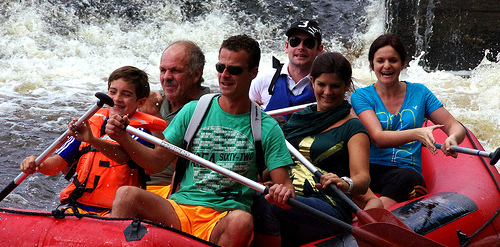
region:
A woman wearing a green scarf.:
[281, 70, 361, 127]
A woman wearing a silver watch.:
[318, 153, 357, 193]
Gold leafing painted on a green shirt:
[293, 124, 345, 187]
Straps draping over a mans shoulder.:
[186, 90, 290, 160]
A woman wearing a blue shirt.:
[362, 77, 430, 189]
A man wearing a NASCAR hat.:
[281, 18, 345, 45]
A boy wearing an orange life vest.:
[63, 92, 142, 214]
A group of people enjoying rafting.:
[72, 33, 493, 223]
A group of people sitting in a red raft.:
[31, 28, 494, 244]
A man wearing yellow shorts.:
[143, 182, 252, 242]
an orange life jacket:
[82, 110, 134, 201]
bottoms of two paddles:
[351, 206, 436, 243]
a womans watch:
[340, 171, 362, 197]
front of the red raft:
[6, 210, 130, 245]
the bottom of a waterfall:
[11, 5, 143, 63]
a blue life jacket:
[274, 73, 311, 123]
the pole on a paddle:
[436, 144, 491, 152]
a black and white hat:
[284, 19, 325, 39]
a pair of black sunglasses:
[286, 33, 323, 51]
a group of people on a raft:
[63, 22, 448, 206]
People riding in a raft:
[1, 14, 498, 243]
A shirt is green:
[161, 92, 298, 213]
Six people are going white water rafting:
[1, 2, 498, 243]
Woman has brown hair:
[364, 30, 410, 83]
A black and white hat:
[282, 14, 328, 49]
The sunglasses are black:
[211, 57, 258, 81]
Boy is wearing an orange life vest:
[55, 61, 169, 210]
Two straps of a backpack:
[172, 89, 269, 194]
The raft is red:
[1, 115, 498, 245]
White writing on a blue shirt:
[350, 80, 448, 176]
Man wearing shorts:
[167, 192, 256, 244]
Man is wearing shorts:
[161, 190, 266, 241]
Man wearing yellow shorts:
[162, 190, 262, 244]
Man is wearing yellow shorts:
[161, 195, 259, 245]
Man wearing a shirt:
[166, 85, 294, 217]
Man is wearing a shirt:
[159, 91, 298, 211]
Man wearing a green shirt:
[160, 87, 294, 213]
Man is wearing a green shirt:
[162, 95, 296, 219]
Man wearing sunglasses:
[211, 55, 263, 75]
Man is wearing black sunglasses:
[215, 59, 257, 75]